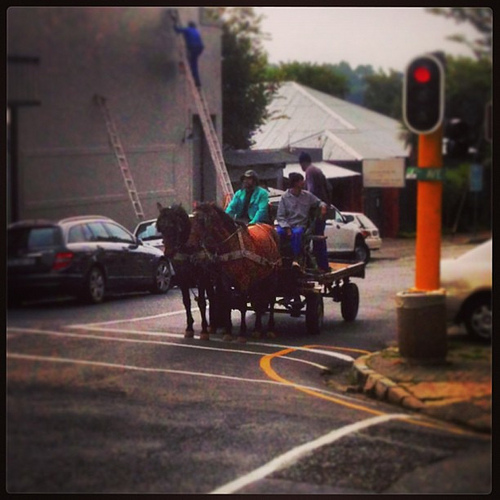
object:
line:
[5, 349, 342, 393]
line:
[6, 325, 328, 370]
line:
[242, 336, 353, 362]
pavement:
[6, 263, 491, 494]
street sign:
[407, 164, 447, 181]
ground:
[331, 213, 354, 240]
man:
[225, 167, 270, 230]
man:
[272, 171, 327, 271]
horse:
[153, 197, 210, 341]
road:
[6, 314, 351, 499]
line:
[204, 414, 395, 496]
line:
[70, 315, 190, 342]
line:
[149, 365, 286, 388]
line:
[8, 323, 55, 339]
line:
[273, 339, 367, 357]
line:
[211, 415, 390, 494]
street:
[0, 252, 496, 496]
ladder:
[168, 7, 236, 205]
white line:
[5, 353, 148, 373]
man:
[174, 15, 207, 100]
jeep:
[322, 212, 382, 265]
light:
[401, 53, 445, 134]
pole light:
[403, 55, 445, 135]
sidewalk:
[2, 302, 477, 498]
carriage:
[273, 256, 367, 333]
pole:
[413, 127, 444, 292]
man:
[297, 150, 335, 273]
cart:
[222, 252, 365, 334]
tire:
[85, 265, 106, 305]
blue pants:
[277, 227, 302, 257]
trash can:
[397, 286, 448, 365]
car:
[3, 214, 173, 305]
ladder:
[93, 92, 146, 225]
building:
[0, 0, 219, 219]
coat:
[225, 186, 270, 225]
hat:
[240, 169, 260, 186]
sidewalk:
[353, 226, 458, 266]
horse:
[184, 201, 285, 345]